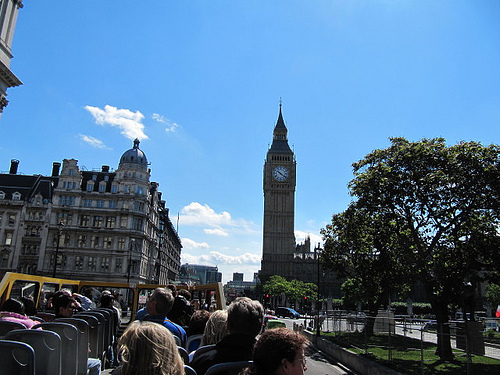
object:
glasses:
[293, 354, 307, 364]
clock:
[271, 167, 289, 181]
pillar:
[261, 148, 296, 275]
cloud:
[73, 132, 109, 149]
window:
[114, 232, 129, 254]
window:
[77, 213, 89, 229]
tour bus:
[1, 271, 254, 372]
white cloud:
[178, 202, 232, 235]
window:
[120, 215, 127, 228]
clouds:
[83, 104, 147, 142]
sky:
[0, 0, 498, 287]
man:
[138, 288, 185, 346]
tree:
[318, 135, 497, 359]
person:
[94, 283, 122, 322]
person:
[194, 298, 266, 373]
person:
[251, 328, 309, 374]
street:
[270, 322, 366, 374]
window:
[83, 196, 91, 208]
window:
[95, 196, 103, 209]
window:
[109, 199, 119, 211]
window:
[113, 254, 123, 272]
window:
[99, 254, 110, 271]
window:
[92, 212, 101, 231]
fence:
[315, 307, 500, 370]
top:
[0, 138, 185, 287]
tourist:
[45, 286, 84, 317]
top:
[272, 95, 289, 139]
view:
[0, 1, 499, 284]